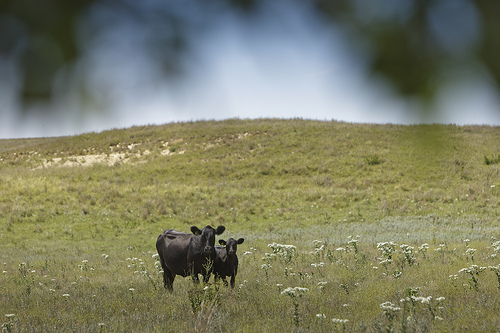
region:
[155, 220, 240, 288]
the cows in the field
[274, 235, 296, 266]
the white flowers by the grass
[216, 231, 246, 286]
the cute little baby cow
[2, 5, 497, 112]
the tree branch on the top of the picture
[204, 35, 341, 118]
the patch of the blue sky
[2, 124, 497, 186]
a grassy hill by the field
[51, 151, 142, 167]
a patch of dirt on the hill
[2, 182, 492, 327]
the grassy field with flowers and cows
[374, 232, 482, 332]
a bunch of white flowers in the field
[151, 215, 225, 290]
the mother cow in the field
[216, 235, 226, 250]
The left ear of the smaller cow.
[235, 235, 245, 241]
The right ear of the smaller cow.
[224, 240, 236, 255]
The head of the smaller cow.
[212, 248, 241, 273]
The body of the smaller cow.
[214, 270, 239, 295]
The legs of the smaller cow.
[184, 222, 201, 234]
The left ear of the larger cow.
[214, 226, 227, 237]
The right ear of the larger cow.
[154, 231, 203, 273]
The body of the larger cow.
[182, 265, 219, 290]
The front legs of the larger cow.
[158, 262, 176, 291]
The back legs of the larger cow.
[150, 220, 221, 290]
cow is black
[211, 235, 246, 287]
calf is black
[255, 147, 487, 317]
land is grassy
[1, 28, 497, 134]
sky is blue and clear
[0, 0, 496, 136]
blurred vegetation seen in foreground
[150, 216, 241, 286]
cows looking towards camera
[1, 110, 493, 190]
top of a hill with grass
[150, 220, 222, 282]
cow is moving tail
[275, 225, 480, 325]
grass is tall and green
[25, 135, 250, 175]
soil is barren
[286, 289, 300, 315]
the plant is white and green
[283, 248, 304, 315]
the plant is white and green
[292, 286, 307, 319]
the plant is white and green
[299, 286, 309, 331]
the plant is white and green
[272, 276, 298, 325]
the plant is white and green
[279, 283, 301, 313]
the plant is white and green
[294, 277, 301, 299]
the plant is white and green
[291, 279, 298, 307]
the plant is white and green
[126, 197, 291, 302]
two black cows in a field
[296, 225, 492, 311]
white flowers in a field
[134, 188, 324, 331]
adult and child cow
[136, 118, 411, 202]
grass on a hill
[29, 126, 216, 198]
dirt patch on hill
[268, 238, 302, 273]
white plant on hill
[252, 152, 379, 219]
dry brush on hill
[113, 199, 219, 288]
cow standing in a field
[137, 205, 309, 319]
cows in dry brush field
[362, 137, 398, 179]
bush on a hill